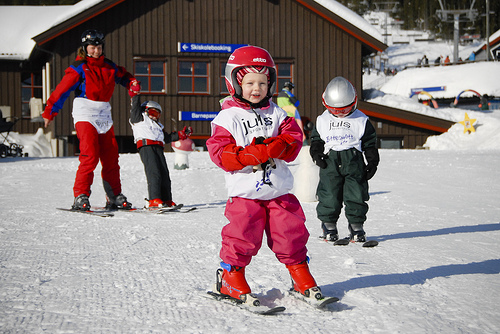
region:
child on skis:
[205, 45, 340, 315]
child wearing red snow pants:
[217, 196, 327, 263]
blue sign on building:
[177, 42, 245, 55]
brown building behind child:
[0, 1, 462, 149]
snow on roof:
[0, 1, 463, 123]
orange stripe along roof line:
[294, 1, 381, 51]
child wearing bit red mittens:
[222, 137, 292, 172]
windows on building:
[135, 59, 164, 91]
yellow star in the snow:
[457, 114, 477, 134]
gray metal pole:
[452, 14, 466, 64]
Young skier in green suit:
[305, 70, 380, 250]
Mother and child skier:
[35, 26, 195, 216]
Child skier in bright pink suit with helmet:
[200, 40, 340, 315]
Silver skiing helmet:
[315, 70, 361, 115]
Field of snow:
[0, 145, 495, 325]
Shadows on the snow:
[310, 220, 495, 311]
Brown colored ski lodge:
[0, 0, 451, 155]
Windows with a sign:
[120, 35, 295, 100]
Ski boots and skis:
[200, 255, 345, 325]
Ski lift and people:
[360, 0, 497, 73]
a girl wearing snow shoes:
[161, 16, 357, 332]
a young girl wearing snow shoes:
[162, 35, 347, 270]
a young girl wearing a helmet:
[183, 10, 326, 307]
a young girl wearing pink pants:
[134, 32, 348, 326]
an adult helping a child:
[39, 11, 185, 239]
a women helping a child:
[30, 6, 193, 221]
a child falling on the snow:
[116, 67, 201, 248]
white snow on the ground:
[37, 221, 144, 331]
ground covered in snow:
[19, 216, 164, 332]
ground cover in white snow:
[8, 200, 175, 332]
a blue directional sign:
[173, 37, 243, 57]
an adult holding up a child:
[38, 28, 194, 224]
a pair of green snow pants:
[307, 149, 374, 231]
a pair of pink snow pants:
[210, 187, 315, 274]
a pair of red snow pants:
[59, 119, 126, 198]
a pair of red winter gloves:
[240, 137, 283, 168]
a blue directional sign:
[170, 107, 217, 122]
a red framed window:
[129, 52, 168, 96]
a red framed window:
[172, 53, 211, 98]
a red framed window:
[16, 65, 43, 105]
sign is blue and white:
[167, 32, 256, 54]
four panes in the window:
[173, 53, 209, 103]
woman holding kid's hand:
[90, 40, 191, 142]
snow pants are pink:
[214, 208, 326, 266]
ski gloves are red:
[236, 131, 318, 184]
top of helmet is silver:
[294, 79, 371, 99]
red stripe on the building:
[311, 7, 412, 71]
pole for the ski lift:
[428, 9, 490, 62]